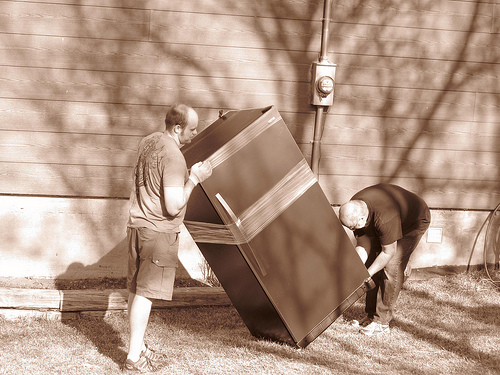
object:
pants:
[364, 224, 427, 325]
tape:
[182, 157, 319, 245]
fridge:
[178, 107, 377, 350]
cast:
[56, 231, 500, 375]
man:
[127, 103, 213, 372]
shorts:
[126, 226, 178, 301]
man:
[339, 183, 430, 333]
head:
[340, 201, 369, 229]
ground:
[0, 263, 499, 374]